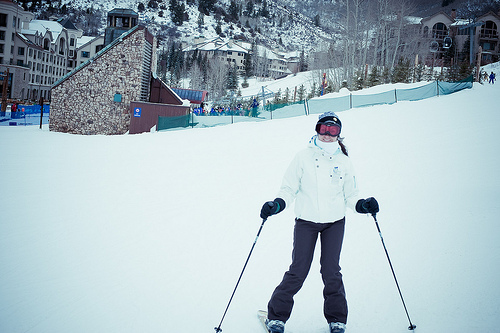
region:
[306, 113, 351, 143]
The woman has goggles on.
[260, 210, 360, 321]
The woman`s pants are black.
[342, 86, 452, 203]
The snow is white.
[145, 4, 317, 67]
The mountains are covered in snow.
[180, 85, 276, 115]
People are gathering outside of a building.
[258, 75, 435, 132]
The fence is green.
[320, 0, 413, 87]
The trees are bare.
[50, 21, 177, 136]
The building is made of stones.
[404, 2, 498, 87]
The building has a lot of windows.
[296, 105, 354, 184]
The woman is smiling.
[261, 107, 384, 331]
woman wearing white coat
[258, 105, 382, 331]
woman holding black skies in both hands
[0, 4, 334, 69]
trees growing on moutain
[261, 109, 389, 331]
woman wearing orange-colored goggles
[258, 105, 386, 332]
woman wearing black pants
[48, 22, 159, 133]
building is made of stone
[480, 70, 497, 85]
kids are playing in snow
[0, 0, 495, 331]
snow is on the ground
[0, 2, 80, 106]
building has multiple stories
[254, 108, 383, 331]
woman is skiing in snow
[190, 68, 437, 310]
the skier is female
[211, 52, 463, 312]
the jacket is white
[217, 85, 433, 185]
the fence is green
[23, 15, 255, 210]
a ski lodge in background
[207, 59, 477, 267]
her pants are black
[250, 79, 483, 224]
her goggles are pink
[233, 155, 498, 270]
she has two poles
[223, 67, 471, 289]
her hair is dark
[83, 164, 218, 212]
the snow is white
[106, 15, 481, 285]
the season is winter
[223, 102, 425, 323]
skier posing for photo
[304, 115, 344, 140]
goggles on woman's face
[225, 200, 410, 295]
two poles in hands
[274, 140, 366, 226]
white jacket on woman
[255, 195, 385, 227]
two gloves on woman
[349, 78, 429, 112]
green fence in snow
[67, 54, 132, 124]
structure made of stone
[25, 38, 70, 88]
windows on front of building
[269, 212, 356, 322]
winter pants on skier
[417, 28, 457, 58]
ski lifts in the air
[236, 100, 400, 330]
Happy skier poses photographer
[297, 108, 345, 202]
Woman wears protective goggles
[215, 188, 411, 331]
Gloved hands grasp ski poles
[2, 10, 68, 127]
Town hotel upper left background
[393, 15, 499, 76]
Large Ski Lodge top right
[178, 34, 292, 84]
Residential apartments mountain slope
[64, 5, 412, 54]
Snow covered hills distance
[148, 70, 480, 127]
Mesh fence surrounds ski area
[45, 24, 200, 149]
Interesting building equipment storage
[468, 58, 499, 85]
Two people walking uphill